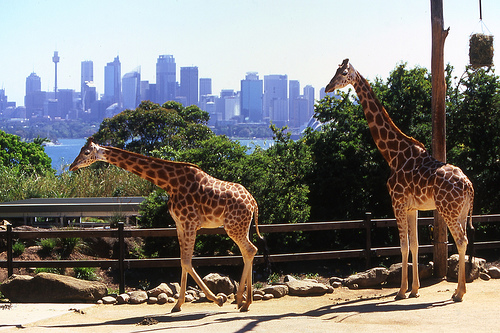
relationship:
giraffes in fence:
[68, 57, 478, 310] [3, 208, 499, 289]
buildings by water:
[3, 50, 321, 134] [32, 138, 299, 169]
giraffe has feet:
[326, 61, 474, 306] [388, 288, 471, 305]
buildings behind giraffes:
[3, 50, 321, 134] [68, 57, 478, 310]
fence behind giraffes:
[3, 208, 499, 289] [68, 57, 478, 310]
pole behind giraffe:
[431, 6, 450, 275] [326, 61, 474, 306]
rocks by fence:
[1, 254, 500, 305] [3, 208, 499, 289]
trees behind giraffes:
[0, 99, 258, 176] [68, 57, 478, 310]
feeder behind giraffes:
[470, 1, 496, 71] [68, 57, 478, 310]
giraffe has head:
[69, 138, 263, 320] [64, 136, 108, 168]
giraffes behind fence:
[68, 57, 478, 310] [3, 208, 499, 289]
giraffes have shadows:
[68, 57, 478, 310] [55, 291, 462, 326]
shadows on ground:
[55, 291, 462, 326] [5, 277, 500, 328]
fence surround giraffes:
[3, 208, 499, 289] [68, 57, 478, 310]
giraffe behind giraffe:
[326, 61, 474, 306] [69, 138, 263, 320]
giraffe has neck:
[69, 138, 263, 320] [102, 145, 174, 189]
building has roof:
[155, 55, 177, 100] [156, 54, 176, 62]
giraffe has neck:
[326, 61, 474, 306] [102, 145, 174, 189]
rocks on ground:
[1, 254, 500, 305] [5, 277, 500, 328]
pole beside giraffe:
[431, 6, 450, 275] [326, 61, 474, 306]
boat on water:
[46, 137, 62, 148] [32, 138, 299, 169]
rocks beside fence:
[1, 254, 500, 305] [3, 208, 499, 289]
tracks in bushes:
[1, 191, 142, 223] [135, 60, 500, 250]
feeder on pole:
[470, 1, 496, 71] [431, 6, 450, 275]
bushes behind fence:
[135, 60, 500, 250] [3, 208, 499, 289]